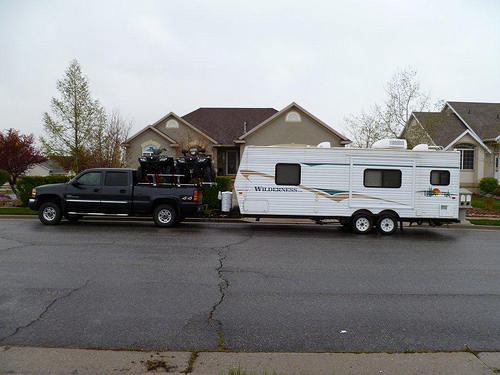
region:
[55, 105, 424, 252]
a truck pulling a camper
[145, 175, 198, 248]
the back wheels on a truck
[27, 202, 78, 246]
the front wheel on a truck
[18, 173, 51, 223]
the headlight on a truck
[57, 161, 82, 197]
a mirror on a truck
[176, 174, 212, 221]
the tail light on a truck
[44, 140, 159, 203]
the side window on a truck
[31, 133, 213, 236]
a truck near a house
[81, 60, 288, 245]
a house near a tree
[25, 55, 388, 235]
a camper near haouse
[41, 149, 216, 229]
black truck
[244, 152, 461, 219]
white trailer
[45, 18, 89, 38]
white clouds in blue sky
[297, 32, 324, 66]
white clouds in blue sky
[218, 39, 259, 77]
white clouds in blue sky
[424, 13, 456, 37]
white clouds in blue sky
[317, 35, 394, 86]
white clouds in blue sky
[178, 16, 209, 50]
white clouds in blue sky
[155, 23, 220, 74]
white clouds in blue sky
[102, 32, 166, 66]
white clouds in blue sky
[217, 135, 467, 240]
White RV attached to the truck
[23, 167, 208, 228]
Silver and black truck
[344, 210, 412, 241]
Two black tires on rv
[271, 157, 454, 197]
Three black windows on rv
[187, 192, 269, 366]
Crack in dark grey road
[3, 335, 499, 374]
Grass growing in crack of road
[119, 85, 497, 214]
Two large beautiful homes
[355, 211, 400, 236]
White wheels on tire for rv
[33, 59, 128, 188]
Large tree next to the house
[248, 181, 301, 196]
Blue lettering on the white rv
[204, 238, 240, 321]
A crack in the pavement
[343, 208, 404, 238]
The wheels of a travel trailer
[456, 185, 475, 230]
A tan mail box near a street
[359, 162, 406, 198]
The side window of a travel trailer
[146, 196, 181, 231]
The left rear wheel of a pickup truck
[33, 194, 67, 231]
The left front wheel of a pickup truck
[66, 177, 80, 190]
The left side mirror of a pickup truck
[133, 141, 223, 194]
Two four wheel vehicles in a pickup truck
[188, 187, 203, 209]
The left rear tail light of a pickup truck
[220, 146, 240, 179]
The front door of a house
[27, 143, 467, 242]
A truck is pulling a trailer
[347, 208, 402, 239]
Two round black wheels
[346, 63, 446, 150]
Trees with no leaves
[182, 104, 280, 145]
The roof of a house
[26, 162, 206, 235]
A truck is black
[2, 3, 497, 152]
The sky appears overcast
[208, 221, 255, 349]
A crack in the road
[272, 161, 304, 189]
A square window on a trailer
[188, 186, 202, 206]
A red rear light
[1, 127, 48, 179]
Red leaves on a tree